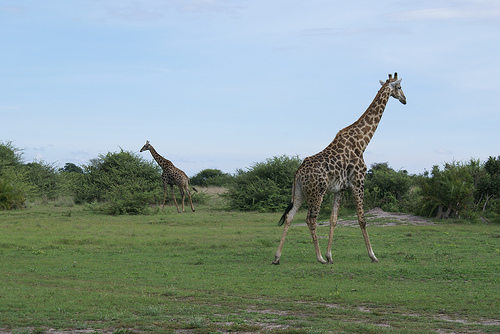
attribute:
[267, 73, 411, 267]
giraffe — walking, tall, standing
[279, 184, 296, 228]
tail — black, long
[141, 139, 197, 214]
giraffe — small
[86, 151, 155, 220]
bush — green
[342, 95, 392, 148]
neck — long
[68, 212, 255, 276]
grass — short, green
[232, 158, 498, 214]
bushes — green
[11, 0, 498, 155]
sky — cloudy, blue, clear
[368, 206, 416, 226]
dirt — brown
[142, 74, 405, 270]
giraffes — walking, tall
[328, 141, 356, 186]
spots — brown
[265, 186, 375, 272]
legs — brown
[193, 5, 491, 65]
clouds — thin